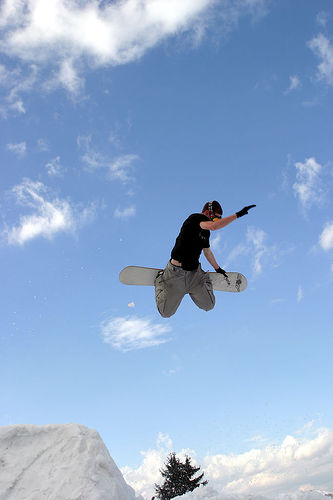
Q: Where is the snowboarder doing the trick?
A: In the air.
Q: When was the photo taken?
A: During daylight.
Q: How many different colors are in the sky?
A: Two.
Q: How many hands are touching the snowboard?
A: One.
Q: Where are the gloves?
A: On his hands.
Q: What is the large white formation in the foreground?
A: Snow.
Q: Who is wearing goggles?
A: Snowboarder.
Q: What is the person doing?
A: Snowboarding.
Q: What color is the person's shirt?
A: Black.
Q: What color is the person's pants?
A: Grey.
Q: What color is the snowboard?
A: Grey.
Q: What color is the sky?
A: Blue.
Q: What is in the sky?
A: Clouds.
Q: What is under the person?
A: Snow.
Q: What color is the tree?
A: Green.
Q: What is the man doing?
A: Performing a trick.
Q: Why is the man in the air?
A: Performing a snowboarding trick.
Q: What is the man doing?
A: A jump.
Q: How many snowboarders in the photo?
A: One.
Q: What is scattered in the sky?
A: Clouds.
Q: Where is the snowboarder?
A: In the air.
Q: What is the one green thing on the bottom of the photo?
A: Green tree.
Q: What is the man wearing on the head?
A: A hat.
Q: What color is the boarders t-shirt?
A: Black.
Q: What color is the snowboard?
A: White.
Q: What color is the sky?
A: Blue.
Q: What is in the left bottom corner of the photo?
A: Snow.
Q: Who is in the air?
A: Snowboarder.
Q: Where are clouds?
A: In the sky.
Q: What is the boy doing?
A: Snowboarding.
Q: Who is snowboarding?
A: The boy.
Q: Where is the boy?
A: In the air.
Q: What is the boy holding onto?
A: The snowboard.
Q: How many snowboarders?
A: 1.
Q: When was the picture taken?
A: Daytime.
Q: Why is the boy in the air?
A: He is snowboarding.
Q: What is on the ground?
A: Snow.